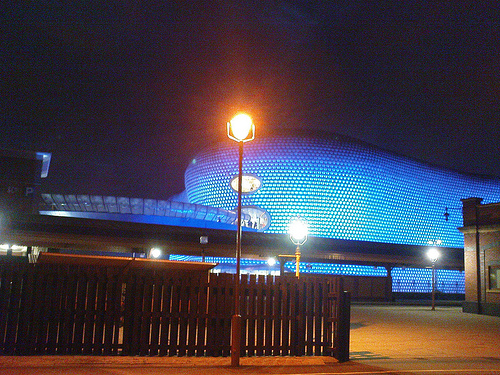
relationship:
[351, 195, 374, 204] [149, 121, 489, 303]
light on building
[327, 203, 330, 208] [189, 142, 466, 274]
light on building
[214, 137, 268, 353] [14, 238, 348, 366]
pole on fence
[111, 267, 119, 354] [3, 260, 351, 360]
pole on fence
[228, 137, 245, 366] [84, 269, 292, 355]
pole on fence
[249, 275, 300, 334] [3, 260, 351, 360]
pole on fence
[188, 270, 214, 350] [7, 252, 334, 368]
pole on fence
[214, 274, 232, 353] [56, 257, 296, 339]
pole on fence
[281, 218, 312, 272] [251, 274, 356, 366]
pole on fence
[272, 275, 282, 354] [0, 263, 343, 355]
pole on fence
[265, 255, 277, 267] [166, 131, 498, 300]
bright light on building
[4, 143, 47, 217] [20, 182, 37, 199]
building with a p sign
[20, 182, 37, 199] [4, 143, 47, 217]
sign on building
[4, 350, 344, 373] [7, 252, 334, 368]
curb in front of fence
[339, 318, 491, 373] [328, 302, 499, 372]
reflection on ground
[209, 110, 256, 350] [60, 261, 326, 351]
street lamp in front of a fence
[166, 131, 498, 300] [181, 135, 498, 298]
building with patterned brickwork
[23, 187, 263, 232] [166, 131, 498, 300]
hallway between building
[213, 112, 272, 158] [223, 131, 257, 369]
light on pole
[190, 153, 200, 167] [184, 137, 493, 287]
light on building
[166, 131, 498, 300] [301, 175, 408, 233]
building on light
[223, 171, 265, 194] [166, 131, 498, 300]
light on building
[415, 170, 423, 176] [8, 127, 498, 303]
light on building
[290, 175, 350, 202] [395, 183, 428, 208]
light on building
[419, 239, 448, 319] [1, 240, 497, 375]
light pole on walkway